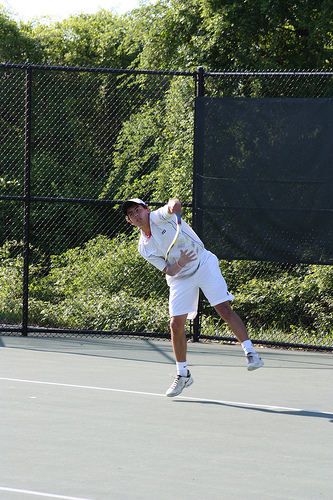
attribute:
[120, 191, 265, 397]
man — dressed, playing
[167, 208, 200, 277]
racket — blue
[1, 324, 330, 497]
court — blue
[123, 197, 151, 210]
cap — white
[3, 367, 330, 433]
lines — white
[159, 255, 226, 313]
shorts — white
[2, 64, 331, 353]
fence — metal, black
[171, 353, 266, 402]
sneakers — white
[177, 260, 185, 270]
wristband — orange, pink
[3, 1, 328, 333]
trees — green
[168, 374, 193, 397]
right foot — white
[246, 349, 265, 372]
left foot — white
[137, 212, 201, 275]
shirt — white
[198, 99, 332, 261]
fabric — black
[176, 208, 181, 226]
handle — blue, red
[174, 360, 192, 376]
sock — white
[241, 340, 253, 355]
sock — white